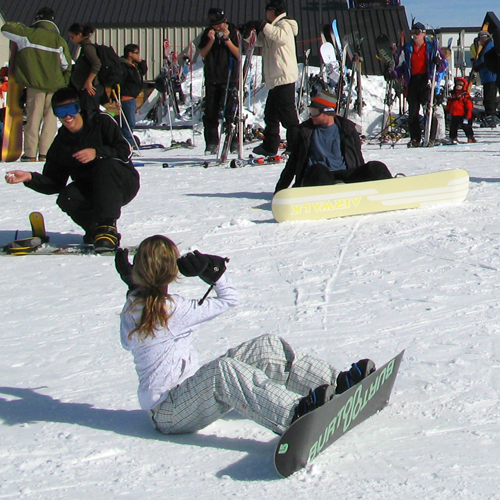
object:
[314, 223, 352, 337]
tracks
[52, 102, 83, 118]
goggles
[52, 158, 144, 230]
pants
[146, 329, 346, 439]
pants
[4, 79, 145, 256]
man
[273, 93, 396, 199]
man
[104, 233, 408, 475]
skier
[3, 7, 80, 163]
skier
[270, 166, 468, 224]
snowboard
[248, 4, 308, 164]
skier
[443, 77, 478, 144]
child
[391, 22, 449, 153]
man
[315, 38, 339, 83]
snowboards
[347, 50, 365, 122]
skiis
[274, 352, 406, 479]
snowboard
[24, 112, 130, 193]
snow attire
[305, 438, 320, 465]
lettering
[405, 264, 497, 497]
snow